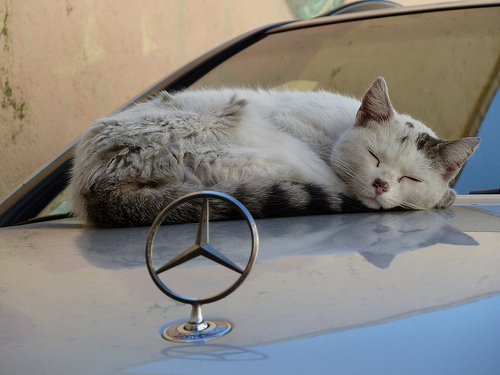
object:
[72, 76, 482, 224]
cat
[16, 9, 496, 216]
windscreen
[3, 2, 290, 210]
wall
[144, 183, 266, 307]
insignia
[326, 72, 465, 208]
head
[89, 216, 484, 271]
reflection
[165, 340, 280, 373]
reflection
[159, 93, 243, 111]
fur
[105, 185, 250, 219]
tail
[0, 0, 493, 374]
car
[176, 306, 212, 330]
small stand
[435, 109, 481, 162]
ears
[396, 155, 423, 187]
eyes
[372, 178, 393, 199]
nose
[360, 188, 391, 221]
mouth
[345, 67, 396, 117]
ear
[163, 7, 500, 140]
windshield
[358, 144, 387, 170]
eye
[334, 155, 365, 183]
whiskers